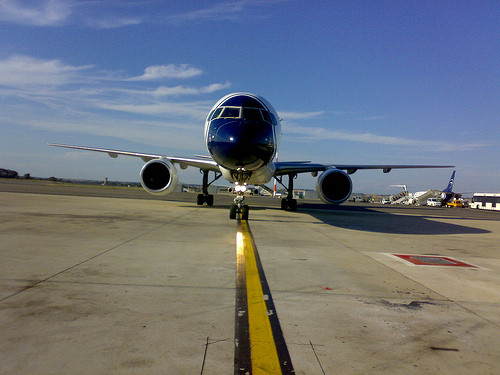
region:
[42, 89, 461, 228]
Airplane on runway of airport.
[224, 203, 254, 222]
Two front landing wheels.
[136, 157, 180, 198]
Engine mounted under right wing.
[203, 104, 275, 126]
Windows across cockpit area.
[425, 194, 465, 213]
Vehicles parked on tarmac service area.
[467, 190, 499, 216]
White bus parked on tarmac in service area.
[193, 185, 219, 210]
Two rear landing wheels.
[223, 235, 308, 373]
Yellow and black line painted on runway.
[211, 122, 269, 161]
Nose cone on front of airplane.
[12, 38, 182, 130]
White clouds in blue sky.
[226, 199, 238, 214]
part of a wheel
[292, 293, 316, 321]
part of a road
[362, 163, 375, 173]
part of a plane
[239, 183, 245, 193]
part of a plane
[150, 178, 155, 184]
part of an engine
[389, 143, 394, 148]
part of the sky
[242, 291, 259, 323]
part of a run way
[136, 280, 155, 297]
part of a road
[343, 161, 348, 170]
part of a wing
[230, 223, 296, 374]
yellow and black strip on the runway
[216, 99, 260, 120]
windows on the plane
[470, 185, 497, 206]
white bus on the side of runway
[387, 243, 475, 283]
red and gray logo on the ground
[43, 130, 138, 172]
wing of the plane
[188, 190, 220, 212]
wheels of the plane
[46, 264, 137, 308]
lines in the road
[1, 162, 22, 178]
trees on the road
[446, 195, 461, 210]
yellow car on the road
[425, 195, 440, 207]
white van on the road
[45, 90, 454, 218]
Airplane on runway.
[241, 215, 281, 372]
Yellow stripe on runway.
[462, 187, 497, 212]
Bus on runway behind airplane.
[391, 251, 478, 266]
Red square on ground.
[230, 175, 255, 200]
Headlights on the front of the plane.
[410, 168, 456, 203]
Airplane in the background.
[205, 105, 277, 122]
Windshield on the airplane.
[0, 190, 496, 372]
Airplane runway.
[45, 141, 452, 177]
Wings of the airplane.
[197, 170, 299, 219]
Landing gear on plane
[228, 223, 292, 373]
yellow and black on the runway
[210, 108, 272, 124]
windows on the plane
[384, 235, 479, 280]
red and gray on the ground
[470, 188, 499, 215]
white bus with windows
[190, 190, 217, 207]
wheels on the plane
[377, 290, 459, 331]
black marks on the runway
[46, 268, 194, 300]
line on the runway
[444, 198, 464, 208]
yellow truck on the runway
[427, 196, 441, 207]
white van on the runway